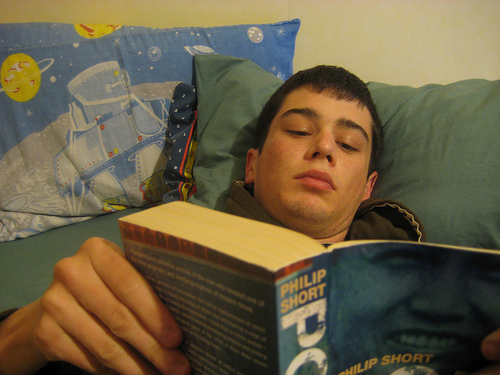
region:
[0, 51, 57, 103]
yellow planet graphic on a pillow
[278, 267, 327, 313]
author's name on the binding of a book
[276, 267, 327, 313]
name print on a book binding reading Philip Short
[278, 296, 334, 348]
bold white letter print on a book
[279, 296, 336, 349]
bold white letter P on a book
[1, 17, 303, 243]
blue print with a space galaxy print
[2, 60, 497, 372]
young man reading a book while laying down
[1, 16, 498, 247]
pillows on a bed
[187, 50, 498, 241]
young man with his head on a pillow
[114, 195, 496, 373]
thick book by Philip Short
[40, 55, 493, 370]
A young boy reading a paper back book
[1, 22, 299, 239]
Blue pillow case with space design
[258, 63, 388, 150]
Brown hair on boy's head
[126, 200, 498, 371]
Thick book in boy's hands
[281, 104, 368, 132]
Black eyebrows on boy's face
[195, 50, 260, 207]
Green pillowcase material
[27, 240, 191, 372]
Boy's hand holding book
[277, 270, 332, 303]
Yellow author name on book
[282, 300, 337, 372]
White letters on book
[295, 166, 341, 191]
Pink lips on boy's face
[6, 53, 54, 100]
Yellow planet picture on pillowcase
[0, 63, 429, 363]
boy lying on bed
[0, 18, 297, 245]
stamped light blue pillow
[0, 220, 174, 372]
right hand holding a book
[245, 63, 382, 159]
short black hair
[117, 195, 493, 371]
big thick book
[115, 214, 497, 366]
blue book cover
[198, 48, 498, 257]
green pillow where boy is lying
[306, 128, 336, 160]
big nose of boy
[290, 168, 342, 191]
little pinky lips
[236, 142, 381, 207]
two small ears of boy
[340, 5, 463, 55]
a light beige wall.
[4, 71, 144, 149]
a blue white grey and yellow pillow.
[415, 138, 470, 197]
a dark green pillow.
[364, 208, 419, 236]
a man is wearing a dark green hoodie jacket.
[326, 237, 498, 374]
a face on the front of a book cover.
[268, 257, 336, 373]
a book is called PHILIP SHORT.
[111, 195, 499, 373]
a thick big book.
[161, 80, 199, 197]
a dark blue red and yellow with dots pillow.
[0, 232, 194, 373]
a mans fingers.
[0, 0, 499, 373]
a man is laying in the bed reading a book.